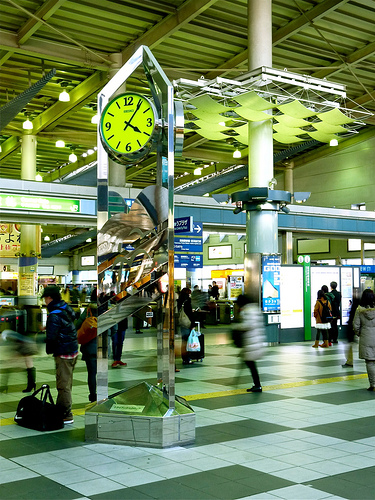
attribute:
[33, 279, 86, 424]
person — standing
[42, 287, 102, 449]
person — walking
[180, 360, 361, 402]
stripe — yellow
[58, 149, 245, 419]
stand — glass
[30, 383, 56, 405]
straps — holding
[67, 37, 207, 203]
arrow — white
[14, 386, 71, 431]
bag — black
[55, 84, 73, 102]
bulb — lit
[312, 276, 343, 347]
people — standing, trio